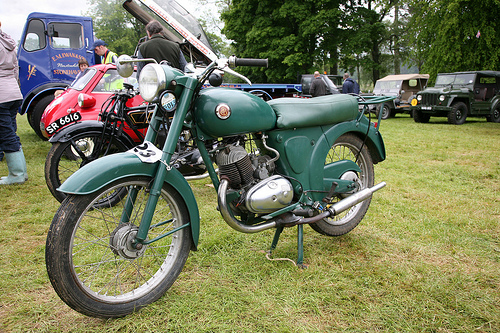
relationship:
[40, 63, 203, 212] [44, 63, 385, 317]
car behind bikes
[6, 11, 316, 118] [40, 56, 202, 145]
truck behind car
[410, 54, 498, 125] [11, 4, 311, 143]
cab of truck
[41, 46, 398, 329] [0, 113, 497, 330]
bike on grass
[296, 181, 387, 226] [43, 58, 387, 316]
pipe on a bike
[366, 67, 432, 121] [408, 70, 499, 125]
cover on jeep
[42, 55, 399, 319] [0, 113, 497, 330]
bike on grass